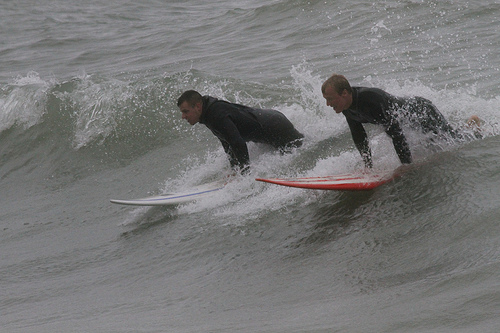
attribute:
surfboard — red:
[251, 172, 396, 193]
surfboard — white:
[106, 177, 243, 210]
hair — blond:
[320, 72, 354, 98]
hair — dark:
[177, 90, 203, 106]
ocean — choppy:
[2, 1, 500, 333]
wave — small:
[2, 63, 499, 328]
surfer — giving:
[321, 73, 484, 174]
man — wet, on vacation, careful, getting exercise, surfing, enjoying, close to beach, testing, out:
[176, 89, 304, 177]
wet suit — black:
[200, 92, 304, 172]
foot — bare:
[464, 111, 486, 144]